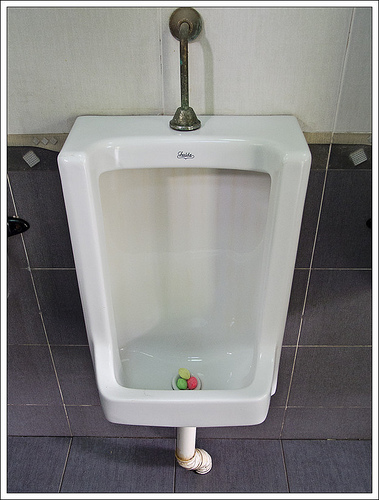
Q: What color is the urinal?
A: White.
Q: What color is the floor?
A: Black.